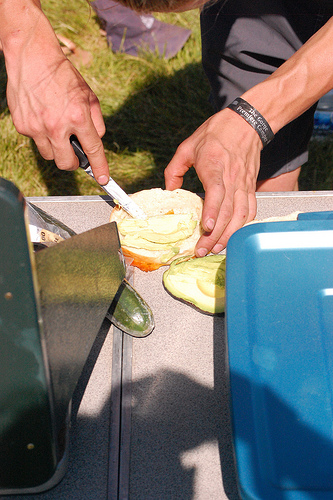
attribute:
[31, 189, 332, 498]
table — grey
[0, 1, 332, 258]
person — nearby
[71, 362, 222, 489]
shadow — dark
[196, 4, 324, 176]
shorts — dark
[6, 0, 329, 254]
man — nearby 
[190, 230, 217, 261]
finger — second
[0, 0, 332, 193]
grass — nearby 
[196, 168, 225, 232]
finger — first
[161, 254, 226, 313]
avacado — halved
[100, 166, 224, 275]
bread — white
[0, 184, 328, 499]
table — grey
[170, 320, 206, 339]
table — picnic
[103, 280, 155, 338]
cucumber — green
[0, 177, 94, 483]
lid — green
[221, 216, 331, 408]
lid — blue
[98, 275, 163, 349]
cucumber — `FRESH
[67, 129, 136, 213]
knife — black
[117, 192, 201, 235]
slice — one of two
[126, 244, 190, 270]
slice — one of two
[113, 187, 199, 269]
slices —  two